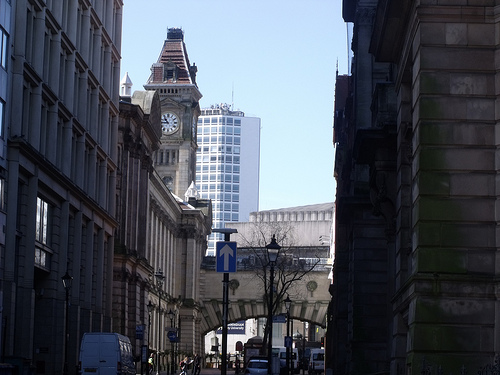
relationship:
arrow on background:
[219, 244, 233, 271] [216, 241, 236, 271]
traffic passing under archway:
[275, 348, 325, 371] [226, 314, 325, 372]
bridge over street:
[198, 267, 333, 328] [117, 342, 330, 372]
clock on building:
[148, 102, 193, 157] [124, 15, 244, 245]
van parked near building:
[80, 330, 145, 373] [17, 5, 143, 351]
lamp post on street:
[263, 232, 284, 370] [164, 341, 243, 372]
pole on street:
[215, 243, 234, 368] [167, 339, 242, 372]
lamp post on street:
[163, 306, 184, 374] [181, 336, 328, 373]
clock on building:
[157, 109, 182, 134] [134, 36, 201, 216]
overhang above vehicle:
[211, 230, 334, 336] [217, 329, 276, 372]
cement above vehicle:
[203, 256, 329, 372] [281, 338, 316, 372]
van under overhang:
[284, 329, 297, 365] [192, 237, 334, 327]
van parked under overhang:
[308, 345, 328, 370] [209, 250, 331, 345]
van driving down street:
[80, 330, 145, 373] [66, 310, 330, 370]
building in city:
[188, 103, 263, 258] [0, 1, 499, 371]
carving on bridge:
[183, 245, 299, 341] [197, 267, 329, 313]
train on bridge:
[191, 216, 326, 272] [197, 267, 329, 313]